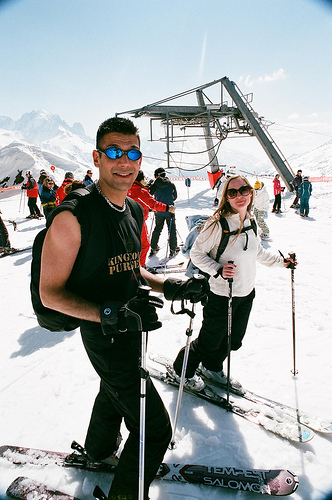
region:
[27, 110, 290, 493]
A guy and girl going skiing.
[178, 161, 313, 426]
A girl going skiing.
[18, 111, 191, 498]
A guy going skiing.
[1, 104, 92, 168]
A gorgeous view of the mountains.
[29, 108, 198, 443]
A guy skiing with no jacket on.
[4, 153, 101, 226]
Lots of people on the ski mountain.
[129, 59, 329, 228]
A ski lift for the mountain and the skiers.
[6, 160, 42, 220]
A guy in a red jacket going down the mountain.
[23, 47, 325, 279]
A beautiful clear day for skiing.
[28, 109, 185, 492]
man standing on skiis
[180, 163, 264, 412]
woman standing on skiis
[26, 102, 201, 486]
man wearing black tank top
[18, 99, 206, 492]
man wearing black pants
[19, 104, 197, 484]
man wearing a silver necklace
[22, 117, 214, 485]
man wearing sunglasses with blue lens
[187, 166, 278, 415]
woman wearing black pants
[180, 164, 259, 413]
woman wearing white sweater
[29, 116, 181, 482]
man carrying a black backpack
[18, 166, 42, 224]
man wearing red and black jacket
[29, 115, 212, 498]
male skier dressed in black wearing blue shades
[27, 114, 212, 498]
male skier wearing a backpack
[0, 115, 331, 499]
man and woman on skis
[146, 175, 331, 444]
woman wearing brown shades and holding skis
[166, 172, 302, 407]
female holding two black skis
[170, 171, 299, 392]
female wearing a white sweater and black pants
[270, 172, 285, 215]
person wearing a red coat and black pants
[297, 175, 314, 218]
person dressed in blue standing in snow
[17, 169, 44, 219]
person wearing a red coat holding skis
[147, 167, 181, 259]
skier wearing black and blue clothing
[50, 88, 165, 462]
skier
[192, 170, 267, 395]
skier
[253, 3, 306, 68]
white clouds in blue sky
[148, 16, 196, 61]
white clouds in blue sky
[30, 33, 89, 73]
white clouds in blue sky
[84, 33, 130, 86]
white clouds in blue sky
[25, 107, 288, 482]
young couple on skis on the top of a mountain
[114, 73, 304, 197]
large grey metal ski lift mechanism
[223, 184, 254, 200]
large framed brown sunglasses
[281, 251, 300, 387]
ski pole with black handle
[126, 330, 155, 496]
silver ski pole the man is holding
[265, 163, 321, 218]
small group of people near the ski lift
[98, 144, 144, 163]
black sunglasses with blue mirrored lenses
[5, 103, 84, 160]
high snow-capped mountains in the distance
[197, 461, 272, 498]
white brand writing on the man's ski